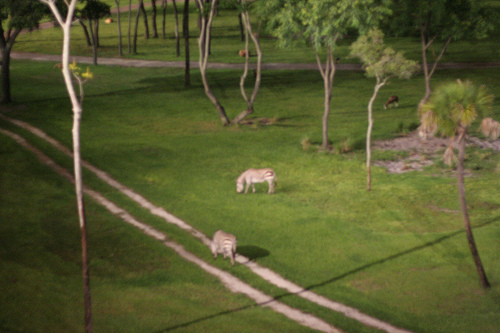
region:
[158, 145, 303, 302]
animals on the grass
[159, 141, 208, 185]
green grass next to animals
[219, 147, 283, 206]
animal with head on ground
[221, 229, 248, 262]
back side of animal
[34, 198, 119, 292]
long branch of tree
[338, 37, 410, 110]
green bush of tree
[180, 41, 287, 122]
brown branches of tree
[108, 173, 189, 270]
two lines on grass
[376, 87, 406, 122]
animal in the background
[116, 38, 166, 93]
road in the background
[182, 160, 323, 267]
Two zebra are shown.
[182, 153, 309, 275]
Two zebra are grazing.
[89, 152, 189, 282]
A pair of tracks are in the grass.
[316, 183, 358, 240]
The grass is green.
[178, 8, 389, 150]
The trees are thin.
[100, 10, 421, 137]
Other animals are in the background.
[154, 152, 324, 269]
The zebras are blurry.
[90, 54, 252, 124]
Shadows are on the ground.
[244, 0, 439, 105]
The trees have leaves.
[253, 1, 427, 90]
The leaves are green.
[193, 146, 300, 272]
two animals on the grass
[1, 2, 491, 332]
oil painting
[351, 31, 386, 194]
tall and skinny tree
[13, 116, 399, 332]
two parallel white lines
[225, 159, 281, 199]
animal grazing in the grass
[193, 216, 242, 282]
animal walking between the two white lines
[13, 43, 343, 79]
narrow path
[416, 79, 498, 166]
green and yellow tree top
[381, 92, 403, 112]
animal standing underneath the trees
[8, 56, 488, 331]
grassy field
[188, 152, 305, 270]
Two zebras in a field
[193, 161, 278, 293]
The zebras are grazing on grass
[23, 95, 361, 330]
There are two tire tracks through the field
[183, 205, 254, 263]
The zebra stands between the tire tracks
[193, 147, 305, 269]
The zebras are black and white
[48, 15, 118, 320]
A tall, narrow tree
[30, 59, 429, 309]
A green grassy field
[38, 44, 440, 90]
A grey cement walkway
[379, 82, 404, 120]
A brown and white animal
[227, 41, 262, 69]
A large beige rock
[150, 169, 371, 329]
the grass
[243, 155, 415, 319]
the grass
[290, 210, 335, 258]
the grass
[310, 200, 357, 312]
the grass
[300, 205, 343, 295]
the grass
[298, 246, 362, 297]
the grass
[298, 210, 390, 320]
the grass